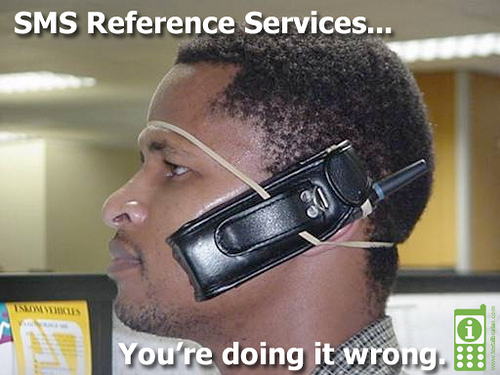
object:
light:
[0, 69, 96, 94]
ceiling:
[0, 0, 497, 140]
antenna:
[372, 158, 429, 200]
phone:
[165, 137, 427, 303]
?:
[461, 282, 471, 287]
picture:
[1, 1, 498, 374]